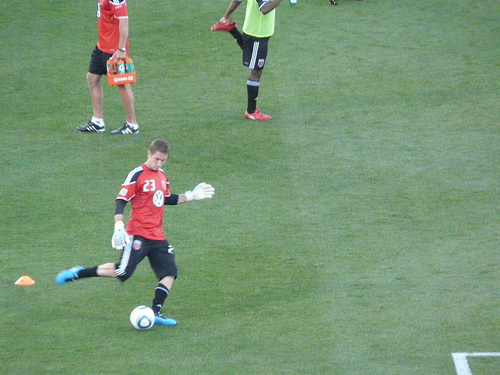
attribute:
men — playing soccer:
[0, 15, 357, 320]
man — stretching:
[203, 1, 298, 123]